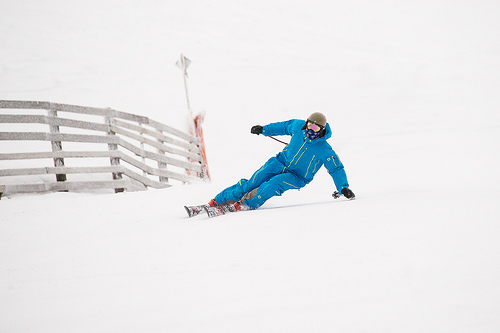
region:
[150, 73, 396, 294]
The man is skiing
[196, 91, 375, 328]
The man is wearing blue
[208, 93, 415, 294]
This is a snowsuit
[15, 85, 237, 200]
This is a fence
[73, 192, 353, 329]
This is a picture of white snow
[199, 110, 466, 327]
The man is on a skii trip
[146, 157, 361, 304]
The man is on two skis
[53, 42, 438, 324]
The picture shows winter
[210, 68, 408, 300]
The man is looking cold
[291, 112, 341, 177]
The man is wearing a helmet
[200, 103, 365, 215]
skier wearing blue suit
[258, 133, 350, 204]
ski poles of skier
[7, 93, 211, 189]
fence covered in snow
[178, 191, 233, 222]
skies at an angle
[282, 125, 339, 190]
yellow accents on blue coat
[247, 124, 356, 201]
black gloves of skier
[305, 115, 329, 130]
helmet of skier wearing blue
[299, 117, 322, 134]
ski goggles of skier wearing blue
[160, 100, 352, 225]
skier skiing at an angle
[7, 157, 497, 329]
snow skier is skiing on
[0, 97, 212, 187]
white rail fence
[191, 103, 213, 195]
an orange end on rail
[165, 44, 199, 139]
raised post at end of fencing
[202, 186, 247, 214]
red ski bindings on skis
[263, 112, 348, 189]
bright blue parka with lime green piping and zippers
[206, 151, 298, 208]
bright blue snow pants with zippered compartments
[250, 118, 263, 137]
black insulated ski glaves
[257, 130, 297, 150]
a brown ski pole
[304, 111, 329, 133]
a brown helmet with black trim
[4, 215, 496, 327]
deep fresh snow on the ground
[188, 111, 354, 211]
man in blue suit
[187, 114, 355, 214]
man on skis leaning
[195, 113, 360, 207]
man in green helmet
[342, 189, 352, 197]
black gloves on man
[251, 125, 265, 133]
black gloves on man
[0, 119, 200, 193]
wooden fence on man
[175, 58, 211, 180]
pole by wooden fence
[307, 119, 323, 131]
google on person's face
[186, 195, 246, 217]
ski's of man in snow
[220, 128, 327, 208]
blue suit of man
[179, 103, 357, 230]
skier is inclined to the right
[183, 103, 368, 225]
skier wears blue snow cloths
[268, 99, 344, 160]
a helmet color brown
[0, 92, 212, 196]
wood fence on side of snow trail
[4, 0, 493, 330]
field is cover with snow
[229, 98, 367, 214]
skier wears black gloves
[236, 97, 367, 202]
man holds snow poles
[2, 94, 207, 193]
fence made of wood planks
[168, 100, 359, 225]
skier falls to his left side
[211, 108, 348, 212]
a blue snow suit with hood